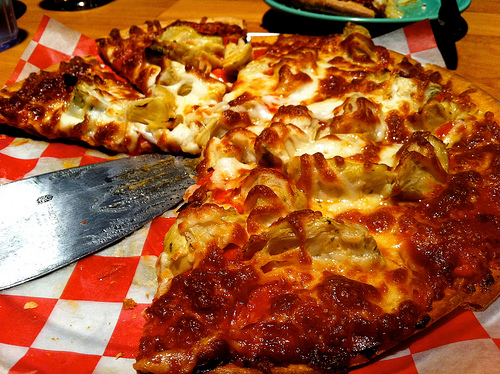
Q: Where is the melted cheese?
A: On pizza.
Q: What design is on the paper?
A: Checkers.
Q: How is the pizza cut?
A: In slices.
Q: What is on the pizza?
A: Cheese.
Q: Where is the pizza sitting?
A: On top of paper.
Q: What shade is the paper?
A: Red and white.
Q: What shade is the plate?
A: Green.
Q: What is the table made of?
A: Wood.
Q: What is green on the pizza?
A: Peppers.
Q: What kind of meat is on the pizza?
A: Chicken.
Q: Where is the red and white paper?
A: Underneath the pizza.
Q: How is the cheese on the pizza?
A: Melted and slightly burnt.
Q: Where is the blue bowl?
A: Behind the pizza.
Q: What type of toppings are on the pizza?
A: Cheese and mushroom.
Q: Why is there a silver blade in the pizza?
A: Spatula used to serve.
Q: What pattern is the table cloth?
A: Red and white checkered.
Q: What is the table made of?
A: Wood.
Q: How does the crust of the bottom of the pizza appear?
A: Blackened.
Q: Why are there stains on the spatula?
A: Grease from pizza.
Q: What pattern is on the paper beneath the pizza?
A: Checkered.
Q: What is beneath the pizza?
A: Checkered paper.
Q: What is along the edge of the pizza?
A: The crust.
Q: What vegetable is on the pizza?
A: Artichokes.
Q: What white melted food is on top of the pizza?
A: Cheese.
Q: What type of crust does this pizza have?
A: Thin crust.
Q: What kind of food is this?
A: A pizze.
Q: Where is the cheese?
A: On the pizze.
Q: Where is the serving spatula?
A: On the table beside the pizze.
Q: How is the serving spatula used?
A: Insert it under the pizza and lift.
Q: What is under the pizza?
A: A checkered paper.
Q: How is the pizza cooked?
A: Baked in oven.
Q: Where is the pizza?
A: On the table.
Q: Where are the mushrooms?
A: On the pizza.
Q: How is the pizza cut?
A: In equal traingles.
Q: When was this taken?
A: At mealtime.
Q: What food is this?
A: Pizza.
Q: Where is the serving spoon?
A: Under the pizza.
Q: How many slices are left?
A: 6.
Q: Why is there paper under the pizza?
A: For grease.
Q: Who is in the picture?
A: No one.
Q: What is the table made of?
A: Wood.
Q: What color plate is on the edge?
A: Teal.